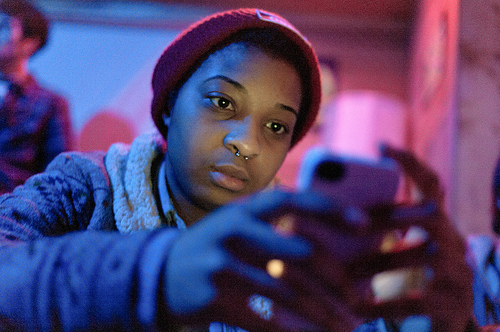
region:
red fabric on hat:
[158, 84, 166, 94]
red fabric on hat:
[161, 63, 170, 68]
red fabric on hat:
[175, 53, 185, 60]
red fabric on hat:
[198, 34, 203, 44]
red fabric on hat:
[209, 25, 217, 36]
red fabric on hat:
[221, 20, 230, 28]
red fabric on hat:
[231, 17, 241, 24]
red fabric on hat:
[253, 20, 261, 25]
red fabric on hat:
[292, 40, 306, 47]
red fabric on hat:
[318, 73, 319, 93]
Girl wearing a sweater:
[0, 23, 472, 330]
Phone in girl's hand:
[268, 143, 432, 328]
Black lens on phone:
[303, 154, 353, 189]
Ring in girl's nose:
[227, 140, 255, 167]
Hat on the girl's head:
[140, 2, 322, 147]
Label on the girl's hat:
[250, 1, 318, 51]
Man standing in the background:
[1, 0, 78, 198]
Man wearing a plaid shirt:
[0, 2, 76, 200]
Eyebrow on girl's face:
[277, 92, 302, 128]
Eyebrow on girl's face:
[197, 65, 254, 93]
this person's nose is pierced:
[207, 130, 278, 170]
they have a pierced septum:
[210, 115, 255, 165]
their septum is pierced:
[215, 130, 276, 170]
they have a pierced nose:
[221, 115, 272, 170]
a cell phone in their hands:
[271, 126, 406, 331]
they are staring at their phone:
[141, 2, 393, 326]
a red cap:
[131, 1, 378, 123]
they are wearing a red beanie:
[130, 2, 364, 282]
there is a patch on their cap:
[250, 3, 340, 56]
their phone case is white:
[291, 122, 408, 327]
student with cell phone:
[0, 28, 481, 326]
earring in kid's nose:
[234, 148, 256, 163]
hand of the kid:
[193, 179, 315, 328]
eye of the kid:
[248, 110, 297, 146]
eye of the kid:
[201, 90, 236, 116]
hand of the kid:
[366, 144, 473, 321]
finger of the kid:
[236, 188, 353, 226]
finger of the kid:
[227, 220, 330, 265]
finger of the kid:
[234, 265, 306, 306]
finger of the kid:
[376, 138, 444, 195]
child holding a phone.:
[244, 140, 419, 330]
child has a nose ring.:
[226, 130, 258, 167]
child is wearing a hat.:
[157, 10, 335, 141]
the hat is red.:
[150, 5, 335, 136]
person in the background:
[1, 0, 71, 186]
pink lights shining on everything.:
[301, 1, 493, 166]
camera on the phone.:
[307, 152, 356, 181]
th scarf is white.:
[96, 123, 176, 234]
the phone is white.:
[265, 149, 406, 327]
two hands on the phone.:
[164, 146, 477, 330]